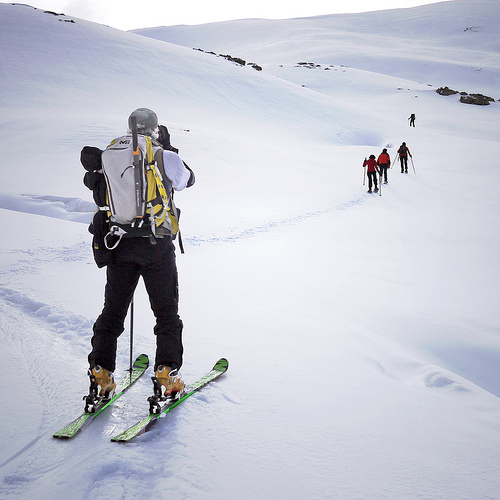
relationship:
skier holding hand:
[85, 107, 195, 399] [156, 124, 172, 147]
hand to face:
[156, 124, 172, 147] [149, 107, 159, 135]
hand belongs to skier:
[156, 124, 172, 147] [85, 107, 195, 399]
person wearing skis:
[394, 138, 410, 173] [366, 186, 380, 195]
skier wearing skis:
[377, 148, 391, 184] [377, 177, 388, 184]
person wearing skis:
[362, 155, 381, 195] [395, 167, 410, 174]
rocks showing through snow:
[197, 44, 267, 75] [27, 24, 172, 95]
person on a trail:
[397, 142, 413, 174] [332, 124, 414, 228]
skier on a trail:
[377, 148, 391, 184] [332, 124, 414, 228]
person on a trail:
[362, 154, 382, 194] [332, 124, 414, 228]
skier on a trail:
[408, 113, 416, 127] [332, 124, 414, 228]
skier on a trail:
[85, 107, 195, 399] [332, 124, 414, 228]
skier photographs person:
[70, 27, 448, 442] [362, 154, 382, 194]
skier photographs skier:
[70, 27, 448, 442] [380, 147, 390, 184]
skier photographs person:
[70, 27, 448, 442] [397, 142, 413, 174]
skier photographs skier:
[70, 27, 448, 442] [408, 112, 418, 128]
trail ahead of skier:
[0, 127, 420, 396] [70, 27, 448, 442]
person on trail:
[362, 154, 382, 194] [0, 127, 420, 396]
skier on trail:
[380, 147, 390, 184] [0, 127, 420, 396]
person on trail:
[397, 142, 413, 174] [0, 127, 420, 396]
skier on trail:
[408, 112, 418, 128] [0, 127, 420, 396]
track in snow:
[315, 203, 362, 218] [44, 17, 477, 378]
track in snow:
[209, 227, 251, 247] [44, 17, 477, 378]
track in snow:
[9, 288, 78, 333] [44, 17, 477, 378]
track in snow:
[27, 181, 90, 232] [44, 17, 477, 378]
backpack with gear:
[76, 118, 190, 277] [57, 112, 219, 318]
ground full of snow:
[5, 2, 498, 497] [2, 2, 498, 499]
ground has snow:
[5, 2, 498, 497] [2, 2, 498, 499]